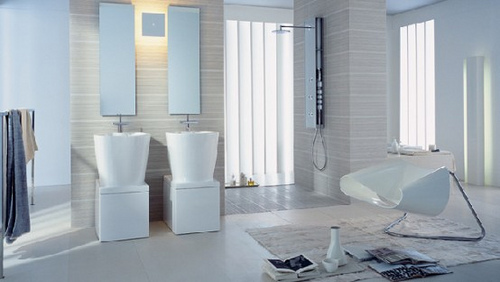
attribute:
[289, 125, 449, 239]
chair — modern, white